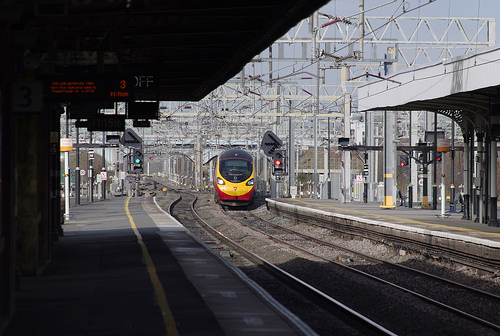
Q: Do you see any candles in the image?
A: No, there are no candles.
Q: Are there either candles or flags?
A: No, there are no candles or flags.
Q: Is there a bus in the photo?
A: No, there are no buses.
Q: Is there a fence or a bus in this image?
A: No, there are no buses or fences.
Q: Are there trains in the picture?
A: Yes, there is a train.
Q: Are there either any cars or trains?
A: Yes, there is a train.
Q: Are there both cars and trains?
A: No, there is a train but no cars.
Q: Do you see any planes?
A: No, there are no planes.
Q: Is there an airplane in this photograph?
A: No, there are no airplanes.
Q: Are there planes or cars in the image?
A: No, there are no planes or cars.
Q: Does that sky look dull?
A: Yes, the sky is dull.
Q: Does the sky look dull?
A: Yes, the sky is dull.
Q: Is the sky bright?
A: No, the sky is dull.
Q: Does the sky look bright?
A: No, the sky is dull.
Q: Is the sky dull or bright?
A: The sky is dull.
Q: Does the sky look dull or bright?
A: The sky is dull.